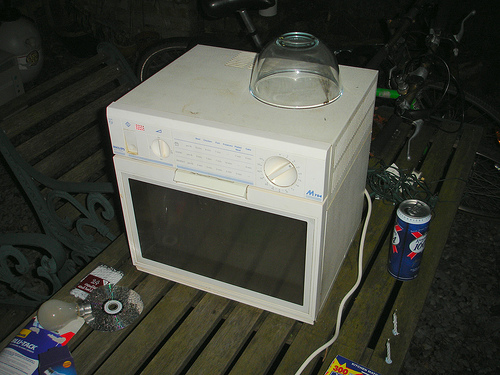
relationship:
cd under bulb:
[78, 282, 144, 333] [36, 293, 93, 330]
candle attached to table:
[383, 307, 403, 342] [12, 106, 488, 373]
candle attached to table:
[383, 338, 393, 364] [12, 106, 488, 373]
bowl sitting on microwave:
[248, 25, 349, 110] [103, 41, 381, 326]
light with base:
[28, 296, 121, 341] [76, 303, 95, 319]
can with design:
[378, 187, 451, 282] [409, 227, 427, 259]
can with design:
[378, 187, 451, 282] [390, 220, 401, 251]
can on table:
[385, 198, 436, 283] [7, 59, 484, 374]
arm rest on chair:
[1, 140, 116, 258] [2, 41, 142, 264]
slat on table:
[376, 108, 481, 373] [58, 291, 419, 373]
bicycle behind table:
[121, 4, 457, 115] [12, 106, 488, 373]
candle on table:
[391, 308, 399, 337] [12, 106, 488, 373]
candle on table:
[383, 340, 392, 362] [12, 106, 488, 373]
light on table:
[36, 296, 120, 332] [12, 106, 488, 373]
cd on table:
[83, 280, 137, 342] [88, 147, 497, 352]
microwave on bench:
[103, 41, 381, 326] [429, 145, 465, 192]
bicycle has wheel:
[128, 0, 499, 222] [117, 33, 217, 77]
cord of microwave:
[294, 187, 371, 372] [103, 41, 381, 326]